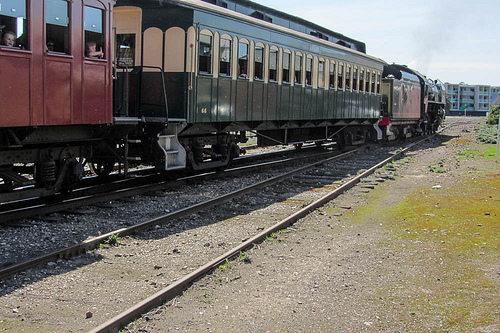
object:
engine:
[382, 60, 448, 143]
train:
[1, 0, 451, 201]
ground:
[230, 262, 307, 303]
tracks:
[97, 199, 212, 273]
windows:
[224, 37, 334, 83]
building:
[444, 81, 499, 112]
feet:
[273, 130, 297, 150]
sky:
[386, 13, 449, 51]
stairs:
[154, 133, 187, 171]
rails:
[275, 10, 321, 40]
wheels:
[31, 138, 84, 190]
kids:
[0, 28, 107, 58]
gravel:
[174, 205, 216, 217]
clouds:
[437, 45, 483, 66]